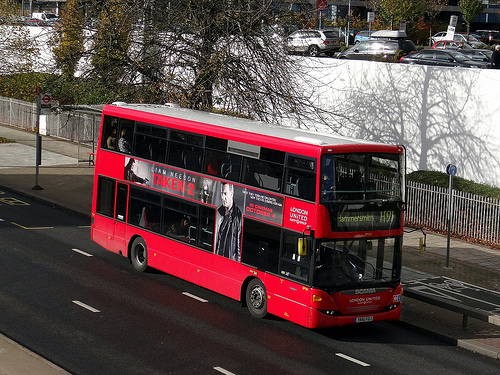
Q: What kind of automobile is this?
A: Bus.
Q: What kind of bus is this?
A: Double decker.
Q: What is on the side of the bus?
A: Advertisement.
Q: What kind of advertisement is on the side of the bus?
A: Movie.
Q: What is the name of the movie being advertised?
A: Taken 2.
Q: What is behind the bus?
A: Fence.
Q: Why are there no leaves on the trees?
A: Not summer.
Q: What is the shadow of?
A: Tree.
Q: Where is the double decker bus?
A: Road.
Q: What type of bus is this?
A: Double decker.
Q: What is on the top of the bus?
A: A white roof.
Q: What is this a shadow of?
A: A tree.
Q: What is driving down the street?
A: A bus.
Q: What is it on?
A: A road.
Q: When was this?
A: Daytime.